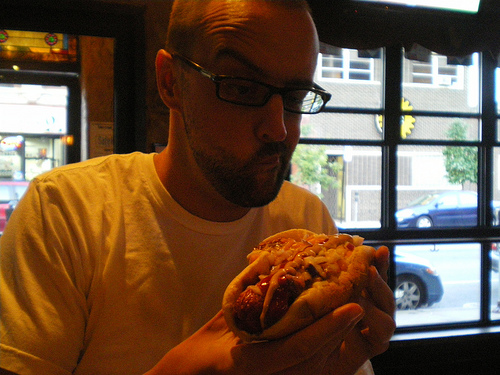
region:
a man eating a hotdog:
[118, 3, 413, 353]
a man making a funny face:
[153, 1, 336, 206]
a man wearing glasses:
[156, 1, 336, 211]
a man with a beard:
[168, 3, 318, 206]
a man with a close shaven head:
[152, 0, 334, 213]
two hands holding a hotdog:
[211, 222, 403, 365]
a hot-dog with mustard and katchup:
[203, 223, 380, 333]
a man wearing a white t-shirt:
[2, 0, 399, 372]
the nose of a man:
[248, 113, 288, 149]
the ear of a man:
[145, 43, 180, 110]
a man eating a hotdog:
[1, 3, 399, 360]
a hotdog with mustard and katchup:
[215, 225, 372, 330]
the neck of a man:
[135, 116, 249, 227]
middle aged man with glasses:
[168, 4, 325, 209]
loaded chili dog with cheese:
[232, 232, 383, 342]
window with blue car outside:
[391, 170, 483, 250]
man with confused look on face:
[170, 5, 332, 206]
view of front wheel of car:
[394, 257, 453, 319]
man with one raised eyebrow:
[197, 33, 342, 174]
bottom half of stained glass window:
[0, 20, 77, 77]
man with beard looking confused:
[162, 11, 329, 213]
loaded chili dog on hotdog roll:
[210, 229, 404, 363]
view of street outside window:
[367, 119, 497, 246]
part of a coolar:
[178, 188, 229, 276]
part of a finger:
[323, 305, 335, 340]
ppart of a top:
[119, 250, 147, 305]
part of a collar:
[172, 188, 229, 279]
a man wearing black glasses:
[122, 3, 349, 227]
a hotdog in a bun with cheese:
[182, 188, 390, 340]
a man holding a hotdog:
[143, 58, 386, 368]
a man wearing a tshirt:
[17, 12, 373, 372]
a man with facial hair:
[148, 14, 352, 231]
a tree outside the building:
[418, 99, 498, 232]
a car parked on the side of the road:
[362, 173, 494, 242]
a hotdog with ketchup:
[189, 210, 379, 337]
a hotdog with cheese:
[198, 192, 403, 344]